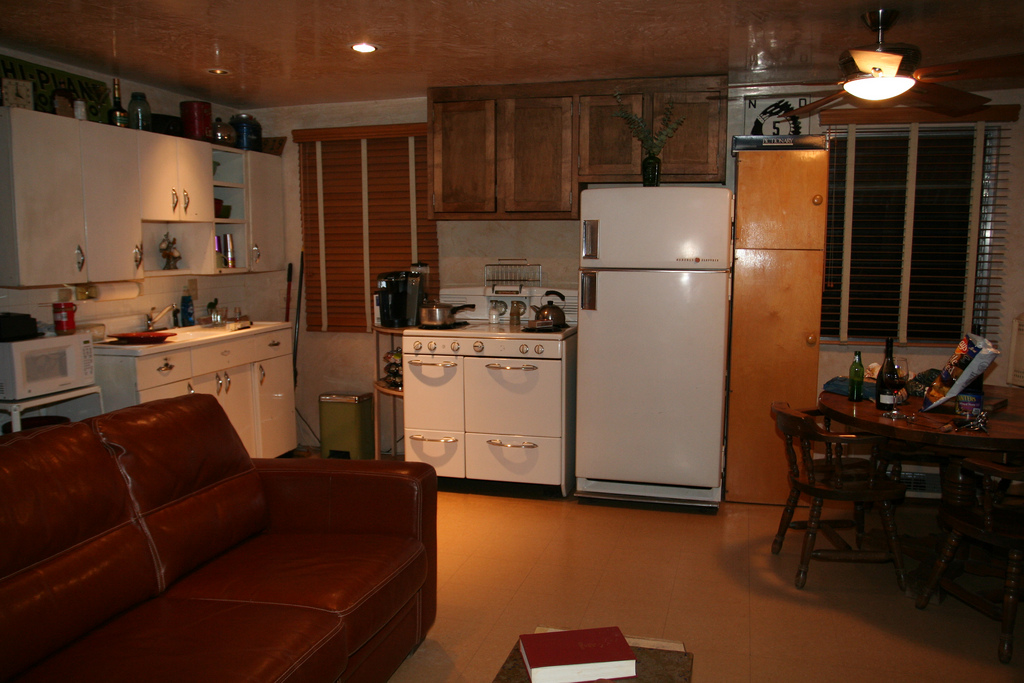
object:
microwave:
[0, 330, 98, 401]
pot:
[419, 299, 476, 331]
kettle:
[529, 290, 565, 328]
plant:
[599, 81, 682, 187]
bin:
[320, 391, 375, 461]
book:
[517, 625, 637, 681]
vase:
[644, 156, 661, 188]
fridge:
[573, 184, 731, 515]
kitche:
[6, 3, 1024, 683]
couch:
[0, 394, 438, 679]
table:
[818, 382, 1021, 580]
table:
[496, 628, 688, 683]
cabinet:
[5, 51, 290, 288]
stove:
[403, 322, 578, 501]